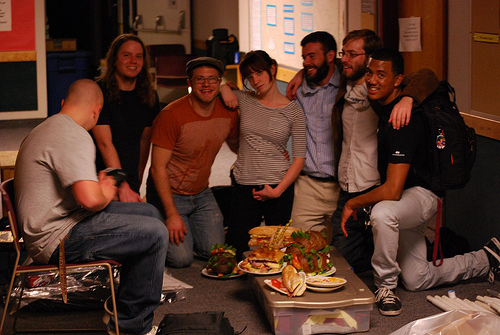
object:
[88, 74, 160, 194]
shirt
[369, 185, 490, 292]
light jeans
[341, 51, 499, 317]
man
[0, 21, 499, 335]
reunion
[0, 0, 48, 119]
board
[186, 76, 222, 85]
glasses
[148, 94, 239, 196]
shirt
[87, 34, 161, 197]
woman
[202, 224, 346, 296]
meal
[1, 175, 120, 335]
chair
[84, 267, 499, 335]
gray flooring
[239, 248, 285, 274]
sandwich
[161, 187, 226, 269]
blue jeans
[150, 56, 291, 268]
man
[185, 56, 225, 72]
hat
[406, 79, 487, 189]
backpack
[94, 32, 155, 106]
hair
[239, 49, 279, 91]
hair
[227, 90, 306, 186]
shirt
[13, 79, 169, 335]
people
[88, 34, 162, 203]
people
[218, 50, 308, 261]
people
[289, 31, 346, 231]
people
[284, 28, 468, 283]
people